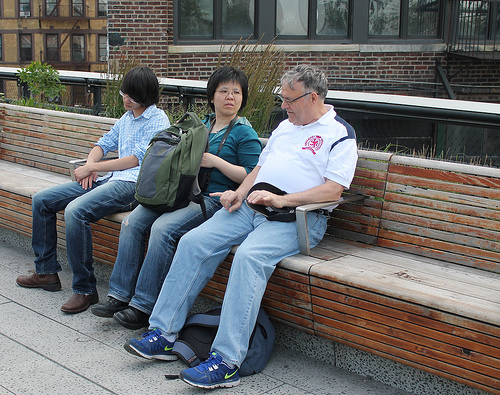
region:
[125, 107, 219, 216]
Green backpack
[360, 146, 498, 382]
Faded wooden bench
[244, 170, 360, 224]
Arm resting on metal armrest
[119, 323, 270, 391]
Blue Nike tennis shoes with green check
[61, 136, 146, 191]
Two arms crossed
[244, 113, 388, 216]
White short sleeved shirt with blue shoulder and red design on front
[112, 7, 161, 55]
Brick wall of a building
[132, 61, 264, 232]
Dark haired woman holding a green backpack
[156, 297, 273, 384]
Backpack on the ground behind someones feet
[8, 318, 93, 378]
Concrete sidewalk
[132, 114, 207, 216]
green backpack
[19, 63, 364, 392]
people sitting on wooden bench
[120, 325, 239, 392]
blue tennis shoes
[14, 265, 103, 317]
brown shoes of man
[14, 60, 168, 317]
boy sitting with hands crossed over each other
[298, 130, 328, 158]
red logo on white shirt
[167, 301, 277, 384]
blue and black backpack on ground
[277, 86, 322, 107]
glasses of old man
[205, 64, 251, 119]
head of woman wearing glasses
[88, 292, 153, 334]
black shoes of woman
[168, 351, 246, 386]
green and blue shoe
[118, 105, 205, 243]
green and gray back pack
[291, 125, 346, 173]
red emblem on shirt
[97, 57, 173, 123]
a person wearing glasses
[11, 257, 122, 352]
a pair of brown shoes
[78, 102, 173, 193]
blue and white shirt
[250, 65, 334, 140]
a person wearing glasses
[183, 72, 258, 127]
a person wearing glasses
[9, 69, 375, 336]
three people sitting on bench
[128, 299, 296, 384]
gray and black back pack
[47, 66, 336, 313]
three people on bench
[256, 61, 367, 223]
guy wearing white shirt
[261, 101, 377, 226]
white shirt with red logo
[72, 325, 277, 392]
blue tennis shoes with green check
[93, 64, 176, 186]
blue and white plaid shirt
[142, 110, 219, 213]
green and black backpack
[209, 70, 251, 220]
black strap around neck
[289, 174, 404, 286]
metal armrest on wood bench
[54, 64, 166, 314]
man wearing blue jeans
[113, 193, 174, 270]
blue jeans with tear in knee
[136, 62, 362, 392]
man sitting on bench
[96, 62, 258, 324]
woman sitting on a bench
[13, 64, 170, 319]
young man sitting on bench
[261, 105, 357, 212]
white shirt with dark blue accent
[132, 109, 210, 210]
backpack on woman's lap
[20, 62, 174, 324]
young man wearing eyeglasses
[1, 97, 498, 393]
wooden bench on which three people are sitting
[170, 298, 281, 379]
man's backpack on ground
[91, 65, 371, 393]
man with gray hair sitting with woman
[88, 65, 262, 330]
Asian woman sitting on bench